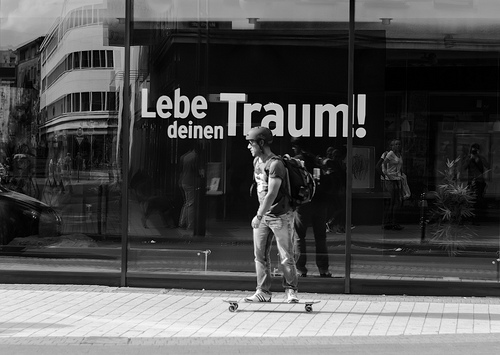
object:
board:
[222, 298, 324, 314]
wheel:
[306, 305, 313, 312]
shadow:
[236, 308, 500, 322]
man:
[243, 126, 300, 303]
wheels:
[305, 305, 313, 313]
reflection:
[171, 141, 209, 231]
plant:
[420, 157, 490, 258]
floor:
[0, 277, 500, 354]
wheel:
[228, 305, 235, 312]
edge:
[2, 267, 498, 298]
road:
[1, 235, 497, 354]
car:
[0, 181, 65, 250]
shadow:
[0, 320, 72, 330]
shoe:
[285, 287, 300, 304]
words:
[140, 87, 156, 118]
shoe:
[244, 289, 273, 303]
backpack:
[282, 154, 317, 206]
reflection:
[375, 140, 414, 232]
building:
[0, 1, 499, 239]